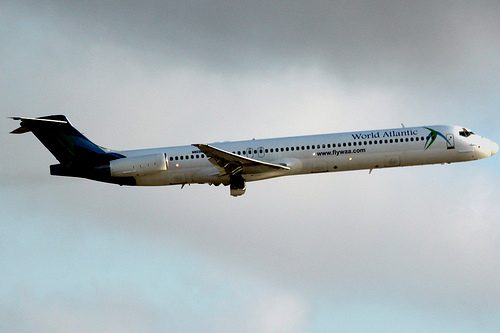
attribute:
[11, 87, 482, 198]
airplane — back , dark tail fin , passenger , flying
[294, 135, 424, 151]
windows — several, row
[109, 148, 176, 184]
engine — large 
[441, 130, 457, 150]
doors — airplane emergency exit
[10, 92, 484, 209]
airplane — white , black 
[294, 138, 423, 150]
windows — cockpit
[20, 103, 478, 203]
airplane — side 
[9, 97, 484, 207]
plane — flying 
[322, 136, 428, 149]
windows — multiple 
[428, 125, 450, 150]
logo — green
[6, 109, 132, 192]
tail — blue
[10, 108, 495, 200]
plane — airborne, horizontal, moving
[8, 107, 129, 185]
tail — black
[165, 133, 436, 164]
windows — aligned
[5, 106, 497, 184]
plane — grey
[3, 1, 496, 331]
sky — cloud-covered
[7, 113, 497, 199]
airplane — in sky,  commercial ,  in air,   in air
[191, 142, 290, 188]
wing —  metal,   airplane's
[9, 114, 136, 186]
tail —  blue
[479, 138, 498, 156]
nose —  white,  airplane's 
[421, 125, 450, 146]
logo —  airplane's 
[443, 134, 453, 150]
door —  closed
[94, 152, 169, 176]
engine —  large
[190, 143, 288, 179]
wing —   airplane's